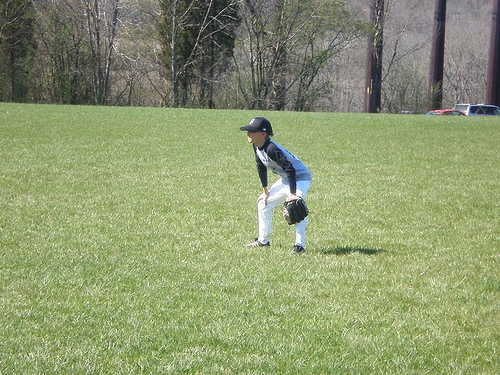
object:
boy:
[238, 116, 314, 253]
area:
[19, 173, 143, 285]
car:
[425, 110, 467, 116]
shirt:
[252, 142, 313, 197]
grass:
[202, 273, 500, 317]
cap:
[239, 117, 274, 136]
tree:
[214, 0, 349, 111]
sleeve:
[266, 143, 297, 195]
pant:
[211, 227, 239, 244]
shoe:
[245, 240, 270, 247]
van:
[452, 103, 499, 118]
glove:
[283, 196, 308, 226]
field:
[157, 108, 212, 162]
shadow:
[312, 245, 386, 256]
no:
[251, 9, 333, 96]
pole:
[364, 82, 371, 113]